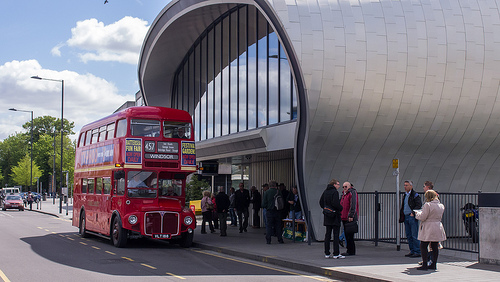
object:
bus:
[47, 104, 204, 244]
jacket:
[414, 196, 449, 243]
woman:
[412, 188, 445, 273]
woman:
[319, 167, 397, 245]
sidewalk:
[304, 233, 386, 280]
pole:
[390, 157, 402, 250]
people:
[302, 182, 391, 265]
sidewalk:
[199, 182, 499, 279]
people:
[180, 177, 310, 237]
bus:
[52, 74, 225, 257]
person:
[319, 176, 345, 258]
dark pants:
[320, 222, 338, 256]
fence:
[360, 190, 396, 244]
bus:
[51, 109, 215, 239]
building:
[136, 0, 498, 244]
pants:
[238, 206, 248, 226]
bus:
[55, 83, 206, 248]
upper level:
[73, 104, 198, 172]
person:
[398, 175, 428, 257]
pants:
[402, 212, 423, 252]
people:
[196, 175, 296, 243]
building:
[128, 11, 473, 192]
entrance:
[202, 156, 253, 205]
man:
[400, 179, 422, 257]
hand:
[408, 213, 413, 217]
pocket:
[408, 215, 415, 222]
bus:
[68, 101, 200, 249]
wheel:
[105, 217, 127, 247]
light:
[32, 70, 72, 212]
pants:
[317, 214, 344, 266]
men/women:
[317, 171, 447, 271]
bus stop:
[177, 159, 499, 280]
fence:
[349, 185, 499, 250]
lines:
[86, 230, 136, 279]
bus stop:
[309, 139, 422, 267]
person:
[245, 181, 273, 243]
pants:
[248, 201, 265, 228]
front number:
[137, 132, 165, 160]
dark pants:
[321, 208, 342, 258]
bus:
[63, 112, 211, 248]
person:
[202, 189, 232, 234]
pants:
[200, 208, 214, 230]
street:
[3, 200, 367, 280]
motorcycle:
[460, 198, 480, 243]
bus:
[125, 136, 152, 168]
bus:
[36, 109, 233, 240]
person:
[210, 177, 227, 237]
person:
[331, 170, 363, 255]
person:
[397, 174, 423, 252]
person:
[415, 182, 435, 274]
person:
[254, 183, 294, 256]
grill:
[141, 206, 186, 240]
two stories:
[71, 92, 195, 244]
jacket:
[329, 169, 364, 254]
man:
[339, 180, 359, 255]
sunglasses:
[340, 184, 347, 189]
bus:
[64, 103, 204, 258]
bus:
[57, 71, 207, 266]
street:
[11, 214, 168, 275]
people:
[189, 159, 449, 269]